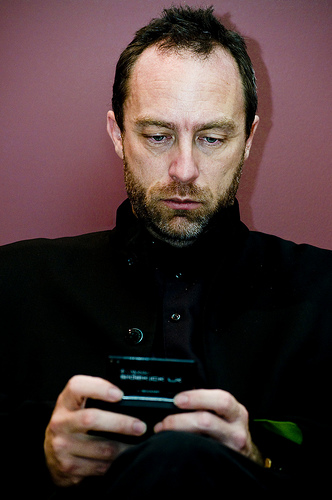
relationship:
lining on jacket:
[254, 414, 306, 444] [1, 197, 329, 495]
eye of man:
[140, 130, 171, 148] [22, 4, 321, 479]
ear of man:
[87, 101, 135, 159] [37, 14, 307, 416]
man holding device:
[1, 4, 331, 498] [92, 341, 198, 435]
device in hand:
[92, 341, 198, 435] [35, 359, 262, 488]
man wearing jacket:
[1, 4, 331, 498] [1, 197, 332, 499]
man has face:
[1, 4, 331, 498] [117, 42, 252, 240]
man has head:
[1, 4, 331, 498] [91, 0, 266, 235]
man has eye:
[1, 4, 331, 498] [199, 131, 224, 145]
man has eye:
[1, 4, 331, 498] [136, 129, 169, 143]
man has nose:
[1, 4, 331, 498] [166, 124, 199, 185]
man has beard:
[1, 4, 331, 498] [123, 159, 244, 247]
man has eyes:
[1, 4, 331, 498] [143, 126, 226, 148]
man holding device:
[1, 4, 331, 498] [97, 358, 204, 426]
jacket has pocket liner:
[1, 197, 329, 495] [246, 412, 304, 445]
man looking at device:
[1, 4, 331, 498] [91, 342, 214, 435]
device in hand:
[89, 341, 198, 443] [43, 372, 149, 490]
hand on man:
[43, 372, 149, 490] [1, 4, 331, 498]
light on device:
[127, 323, 146, 343] [89, 341, 198, 443]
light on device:
[104, 352, 193, 363] [89, 341, 198, 443]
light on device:
[118, 394, 173, 401] [89, 341, 198, 443]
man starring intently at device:
[1, 4, 331, 498] [87, 254, 199, 445]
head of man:
[104, 0, 260, 240] [1, 4, 331, 498]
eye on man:
[199, 134, 222, 144] [1, 4, 331, 498]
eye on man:
[140, 132, 171, 142] [1, 4, 331, 498]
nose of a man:
[168, 126, 199, 180] [1, 4, 331, 498]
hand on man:
[43, 372, 149, 478] [1, 4, 331, 498]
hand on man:
[152, 386, 262, 467] [1, 4, 331, 498]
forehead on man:
[127, 38, 244, 129] [1, 4, 331, 498]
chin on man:
[143, 203, 211, 241] [1, 4, 331, 498]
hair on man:
[110, 0, 257, 143] [1, 4, 331, 498]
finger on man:
[172, 387, 239, 422] [1, 4, 331, 498]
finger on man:
[152, 411, 233, 442] [1, 4, 331, 498]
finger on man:
[55, 372, 125, 400] [1, 4, 331, 498]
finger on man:
[62, 410, 148, 434] [1, 4, 331, 498]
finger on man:
[64, 435, 129, 459] [1, 4, 331, 498]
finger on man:
[64, 450, 110, 475] [1, 4, 331, 498]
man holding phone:
[1, 4, 331, 498] [90, 286, 208, 445]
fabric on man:
[250, 415, 308, 448] [1, 4, 331, 498]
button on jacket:
[172, 266, 186, 282] [1, 197, 332, 499]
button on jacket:
[166, 309, 185, 324] [1, 197, 332, 499]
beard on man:
[123, 159, 244, 250] [1, 4, 331, 498]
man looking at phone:
[1, 4, 331, 498] [80, 257, 197, 447]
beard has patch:
[123, 159, 244, 247] [185, 216, 208, 238]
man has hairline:
[1, 4, 331, 498] [113, 17, 249, 122]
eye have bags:
[140, 130, 171, 148] [146, 142, 226, 152]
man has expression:
[1, 4, 331, 498] [130, 105, 240, 235]